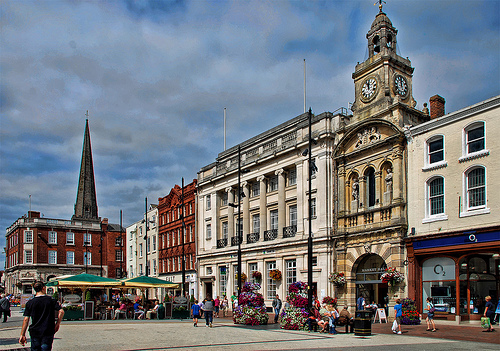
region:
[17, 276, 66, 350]
Man wearing a black shirt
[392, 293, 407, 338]
Woman wearing a blue shirt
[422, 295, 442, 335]
Woman walking on sidewalk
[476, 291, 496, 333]
Woman carrying a shopping bag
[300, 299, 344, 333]
People sitting on a bench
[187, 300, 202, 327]
Boy wearing a blue shirt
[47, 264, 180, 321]
Canopies over a table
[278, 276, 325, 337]
Flowers on the sidewalk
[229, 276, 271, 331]
Flowers on the sidewalk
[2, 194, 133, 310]
Building in the background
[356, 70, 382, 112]
Clock on top of the tower.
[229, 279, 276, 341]
Flowers on the walkway.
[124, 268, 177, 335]
People sitting under the umbrella.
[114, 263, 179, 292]
The umbrella is green.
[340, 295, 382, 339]
A garbage can on sidewalk.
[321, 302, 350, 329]
Person sitting on the bench.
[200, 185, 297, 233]
Windows on the building.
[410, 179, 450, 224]
The window pane is white.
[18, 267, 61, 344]
A person walking on the street.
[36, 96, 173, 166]
The sky is blue and cloudy.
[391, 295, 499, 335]
people walking on the walk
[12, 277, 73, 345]
man walking toward district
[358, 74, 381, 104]
clock on the tower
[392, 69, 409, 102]
clock on the tower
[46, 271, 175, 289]
tents over seating area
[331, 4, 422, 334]
building with clock on it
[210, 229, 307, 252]
bars on the window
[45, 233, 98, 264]
windows on the buildings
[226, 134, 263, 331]
pole on the walk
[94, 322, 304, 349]
concrete on center of district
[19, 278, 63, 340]
Man wearing a short black t shirt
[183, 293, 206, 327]
A young boy in a blue shirt walking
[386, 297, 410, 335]
A person in a blue shirt carrying a white bag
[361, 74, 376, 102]
A white clock face with black hands and writing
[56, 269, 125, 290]
Top of a tan and turquoise tent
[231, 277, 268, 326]
Colorful arrangement or red, green, and purple flowers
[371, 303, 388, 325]
White sign standing on the street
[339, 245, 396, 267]
Arching door of a building in tan and brown brick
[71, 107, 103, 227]
Tall dark gray spire of a building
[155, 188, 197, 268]
Large red brick building with many windows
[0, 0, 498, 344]
Line of large buildings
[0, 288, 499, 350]
People on the walkway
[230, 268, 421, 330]
Heaps of blooming flower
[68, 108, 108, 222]
Tapering building with a crucifix at the top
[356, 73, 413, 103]
Two large clock on a building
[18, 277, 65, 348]
Man in a black shirt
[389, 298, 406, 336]
Person carrying a white bag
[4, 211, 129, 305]
Building made of red bricks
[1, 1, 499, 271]
Blue sky filled with clouds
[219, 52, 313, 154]
Flag masts at the top of a building